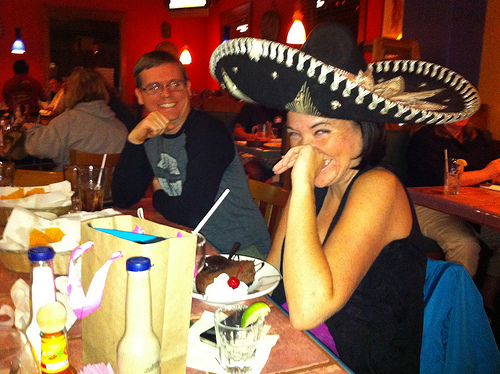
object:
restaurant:
[1, 2, 499, 373]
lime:
[240, 302, 271, 326]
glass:
[214, 304, 265, 374]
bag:
[81, 215, 197, 373]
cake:
[196, 256, 256, 290]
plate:
[192, 252, 281, 306]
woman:
[208, 26, 478, 373]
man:
[110, 49, 272, 261]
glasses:
[138, 81, 187, 94]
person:
[22, 68, 128, 170]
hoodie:
[23, 100, 127, 170]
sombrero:
[209, 21, 481, 123]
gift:
[90, 225, 167, 245]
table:
[0, 197, 357, 374]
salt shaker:
[27, 247, 57, 363]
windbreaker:
[424, 259, 499, 373]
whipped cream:
[202, 273, 249, 305]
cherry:
[229, 266, 242, 288]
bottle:
[36, 303, 69, 374]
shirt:
[110, 108, 271, 255]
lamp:
[11, 26, 27, 55]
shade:
[12, 41, 25, 55]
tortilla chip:
[30, 227, 51, 246]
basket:
[1, 211, 122, 274]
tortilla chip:
[45, 226, 65, 243]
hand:
[271, 144, 326, 178]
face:
[286, 113, 355, 188]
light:
[234, 24, 249, 33]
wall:
[191, 21, 211, 84]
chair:
[421, 258, 474, 374]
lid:
[126, 255, 151, 270]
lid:
[28, 246, 55, 260]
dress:
[272, 167, 423, 373]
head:
[132, 51, 192, 122]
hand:
[135, 110, 176, 140]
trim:
[359, 56, 481, 125]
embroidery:
[284, 81, 322, 117]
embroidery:
[219, 66, 256, 104]